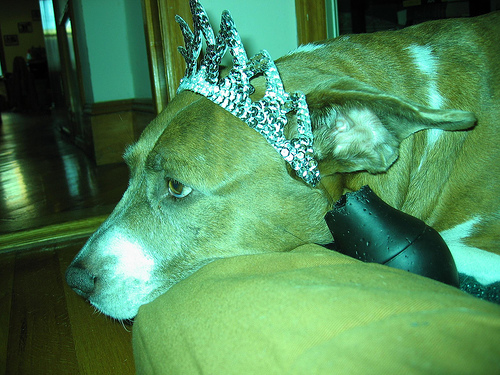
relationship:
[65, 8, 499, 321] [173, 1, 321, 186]
dog in a tiara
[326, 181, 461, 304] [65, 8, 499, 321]
toy beside dog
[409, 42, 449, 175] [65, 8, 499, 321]
patch on dog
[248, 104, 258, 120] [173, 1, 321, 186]
diamnd on tiara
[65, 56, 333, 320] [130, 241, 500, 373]
head resting on couch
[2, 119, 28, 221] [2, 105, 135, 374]
reflection on floor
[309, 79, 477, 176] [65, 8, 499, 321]
left ear of dog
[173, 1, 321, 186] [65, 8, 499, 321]
tiara on dog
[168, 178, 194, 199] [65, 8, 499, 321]
eye on dog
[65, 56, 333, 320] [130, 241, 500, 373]
head of dog on couch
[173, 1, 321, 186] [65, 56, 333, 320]
tiara on head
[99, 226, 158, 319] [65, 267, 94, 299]
patch on nose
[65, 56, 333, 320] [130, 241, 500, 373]
head on arm of couch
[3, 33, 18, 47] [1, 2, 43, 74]
picture on wall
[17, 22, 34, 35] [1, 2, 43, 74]
picture on wall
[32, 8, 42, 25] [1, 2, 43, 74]
picture on wall